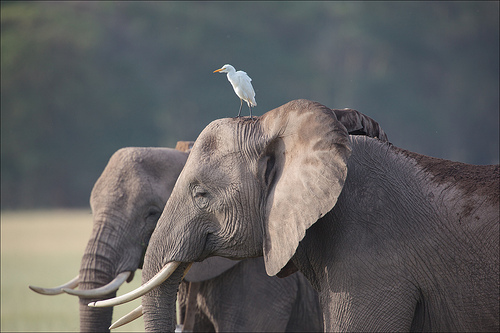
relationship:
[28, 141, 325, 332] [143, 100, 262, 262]
elephant has head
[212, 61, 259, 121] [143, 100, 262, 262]
bird on head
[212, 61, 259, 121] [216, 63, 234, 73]
bird has head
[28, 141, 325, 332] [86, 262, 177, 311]
elephant has trunk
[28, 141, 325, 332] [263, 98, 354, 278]
elephant has ear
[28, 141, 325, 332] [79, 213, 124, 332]
elephant has trunk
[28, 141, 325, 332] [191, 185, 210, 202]
elephant has eye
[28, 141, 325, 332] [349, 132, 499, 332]
elephant has back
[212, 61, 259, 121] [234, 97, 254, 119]
bird has legs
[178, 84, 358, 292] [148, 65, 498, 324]
head of an elephant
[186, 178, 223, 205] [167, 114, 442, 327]
eye of an elephant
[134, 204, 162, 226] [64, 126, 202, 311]
eye of an elephant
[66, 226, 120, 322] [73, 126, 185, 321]
nose of an elephant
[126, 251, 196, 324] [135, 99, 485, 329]
nose of an elephant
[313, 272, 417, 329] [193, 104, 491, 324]
leg of an elephant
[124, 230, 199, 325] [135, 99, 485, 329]
trunk of an elephant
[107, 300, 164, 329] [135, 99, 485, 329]
trunk of an elephant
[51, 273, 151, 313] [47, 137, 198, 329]
trunk of an elephant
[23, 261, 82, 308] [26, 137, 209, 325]
trunk of an elephant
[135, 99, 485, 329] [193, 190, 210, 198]
elephant throws eye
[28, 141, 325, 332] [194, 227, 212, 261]
elephant has mouth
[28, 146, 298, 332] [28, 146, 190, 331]
elephant has head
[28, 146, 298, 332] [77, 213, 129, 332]
elephant has trunk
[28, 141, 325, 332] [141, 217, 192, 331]
elephant has trunk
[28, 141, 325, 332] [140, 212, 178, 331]
elephant has trunk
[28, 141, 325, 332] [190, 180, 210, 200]
elephant has eye